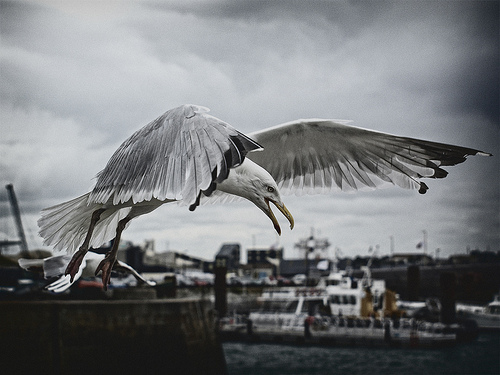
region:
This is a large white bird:
[140, 68, 287, 266]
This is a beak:
[254, 193, 329, 250]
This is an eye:
[248, 173, 297, 199]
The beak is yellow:
[240, 185, 310, 245]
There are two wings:
[98, 115, 312, 279]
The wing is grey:
[164, 126, 274, 167]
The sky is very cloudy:
[105, 58, 243, 140]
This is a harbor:
[144, 273, 324, 358]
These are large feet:
[64, 232, 159, 357]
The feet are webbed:
[68, 231, 210, 362]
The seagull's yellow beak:
[255, 198, 300, 244]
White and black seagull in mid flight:
[38, 84, 495, 286]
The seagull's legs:
[65, 205, 131, 287]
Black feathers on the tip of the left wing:
[406, 126, 491, 206]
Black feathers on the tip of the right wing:
[188, 126, 261, 224]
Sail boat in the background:
[217, 256, 497, 340]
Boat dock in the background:
[1, 6, 491, 368]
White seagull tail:
[30, 187, 138, 257]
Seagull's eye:
[266, 184, 276, 195]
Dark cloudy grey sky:
[0, 2, 497, 251]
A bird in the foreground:
[31, 98, 496, 288]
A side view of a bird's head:
[227, 168, 303, 238]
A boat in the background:
[243, 280, 464, 350]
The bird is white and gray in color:
[16, 91, 495, 294]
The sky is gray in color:
[3, 0, 499, 256]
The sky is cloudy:
[6, 5, 498, 262]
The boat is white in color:
[236, 288, 463, 348]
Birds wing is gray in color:
[95, 105, 269, 221]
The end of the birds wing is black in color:
[166, 127, 486, 232]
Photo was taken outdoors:
[2, 1, 498, 373]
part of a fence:
[156, 291, 198, 350]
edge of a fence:
[152, 280, 188, 326]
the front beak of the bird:
[266, 203, 298, 230]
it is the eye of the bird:
[266, 186, 278, 194]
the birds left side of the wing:
[119, 128, 223, 203]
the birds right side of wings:
[277, 118, 370, 175]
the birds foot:
[97, 258, 122, 285]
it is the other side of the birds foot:
[61, 248, 93, 278]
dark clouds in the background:
[50, 21, 211, 95]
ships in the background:
[266, 278, 363, 337]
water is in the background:
[250, 338, 305, 371]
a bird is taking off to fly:
[77, 109, 394, 315]